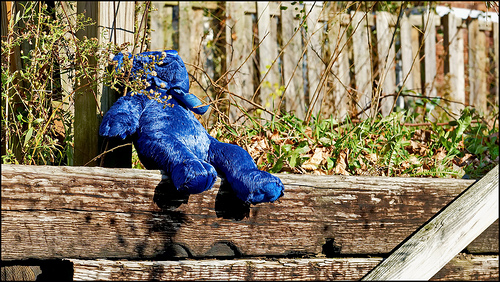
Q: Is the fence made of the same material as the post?
A: Yes, both the fence and the post are made of wood.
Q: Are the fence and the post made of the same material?
A: Yes, both the fence and the post are made of wood.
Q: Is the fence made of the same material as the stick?
A: Yes, both the fence and the stick are made of wood.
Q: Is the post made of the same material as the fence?
A: Yes, both the post and the fence are made of wood.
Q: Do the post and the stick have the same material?
A: Yes, both the post and the stick are made of wood.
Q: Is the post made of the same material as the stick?
A: Yes, both the post and the stick are made of wood.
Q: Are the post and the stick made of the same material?
A: Yes, both the post and the stick are made of wood.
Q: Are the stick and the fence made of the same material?
A: Yes, both the stick and the fence are made of wood.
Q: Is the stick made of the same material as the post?
A: Yes, both the stick and the post are made of wood.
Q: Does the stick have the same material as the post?
A: Yes, both the stick and the post are made of wood.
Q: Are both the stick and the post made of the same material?
A: Yes, both the stick and the post are made of wood.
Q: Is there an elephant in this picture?
A: Yes, there is an elephant.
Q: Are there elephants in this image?
A: Yes, there is an elephant.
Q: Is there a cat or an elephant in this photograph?
A: Yes, there is an elephant.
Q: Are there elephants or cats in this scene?
A: Yes, there is an elephant.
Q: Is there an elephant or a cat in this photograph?
A: Yes, there is an elephant.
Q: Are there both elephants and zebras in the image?
A: No, there is an elephant but no zebras.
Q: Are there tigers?
A: No, there are no tigers.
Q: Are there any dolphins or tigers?
A: No, there are no tigers or dolphins.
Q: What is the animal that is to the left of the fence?
A: The animal is an elephant.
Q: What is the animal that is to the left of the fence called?
A: The animal is an elephant.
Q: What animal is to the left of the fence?
A: The animal is an elephant.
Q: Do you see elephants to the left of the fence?
A: Yes, there is an elephant to the left of the fence.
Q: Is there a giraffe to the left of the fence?
A: No, there is an elephant to the left of the fence.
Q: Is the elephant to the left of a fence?
A: Yes, the elephant is to the left of a fence.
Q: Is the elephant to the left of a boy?
A: No, the elephant is to the left of a fence.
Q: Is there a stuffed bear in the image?
A: Yes, there is a stuffed bear.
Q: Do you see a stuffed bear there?
A: Yes, there is a stuffed bear.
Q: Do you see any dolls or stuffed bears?
A: Yes, there is a stuffed bear.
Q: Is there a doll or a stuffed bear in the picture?
A: Yes, there is a stuffed bear.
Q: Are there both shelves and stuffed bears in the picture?
A: No, there is a stuffed bear but no shelves.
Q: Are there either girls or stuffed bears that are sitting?
A: Yes, the stuffed bear is sitting.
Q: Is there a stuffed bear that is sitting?
A: Yes, there is a stuffed bear that is sitting.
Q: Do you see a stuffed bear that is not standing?
A: Yes, there is a stuffed bear that is sitting .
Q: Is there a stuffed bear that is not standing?
A: Yes, there is a stuffed bear that is sitting.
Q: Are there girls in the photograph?
A: No, there are no girls.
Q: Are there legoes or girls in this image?
A: No, there are no girls or legoes.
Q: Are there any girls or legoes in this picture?
A: No, there are no girls or legoes.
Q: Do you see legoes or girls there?
A: No, there are no girls or legoes.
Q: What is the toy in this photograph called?
A: The toy is a stuffed bear.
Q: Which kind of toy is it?
A: The toy is a stuffed bear.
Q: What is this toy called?
A: This is a stuffed bear.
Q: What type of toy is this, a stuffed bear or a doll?
A: This is a stuffed bear.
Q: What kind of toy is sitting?
A: The toy is a stuffed bear.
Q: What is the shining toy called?
A: The toy is a stuffed bear.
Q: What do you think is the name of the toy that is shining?
A: The toy is a stuffed bear.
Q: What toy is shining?
A: The toy is a stuffed bear.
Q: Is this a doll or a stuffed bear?
A: This is a stuffed bear.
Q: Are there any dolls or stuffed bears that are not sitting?
A: No, there is a stuffed bear but it is sitting.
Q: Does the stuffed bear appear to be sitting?
A: Yes, the stuffed bear is sitting.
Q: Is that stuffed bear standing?
A: No, the stuffed bear is sitting.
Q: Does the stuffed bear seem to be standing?
A: No, the stuffed bear is sitting.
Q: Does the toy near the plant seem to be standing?
A: No, the stuffed bear is sitting.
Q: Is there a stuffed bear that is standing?
A: No, there is a stuffed bear but it is sitting.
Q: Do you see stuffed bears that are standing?
A: No, there is a stuffed bear but it is sitting.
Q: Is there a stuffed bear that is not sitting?
A: No, there is a stuffed bear but it is sitting.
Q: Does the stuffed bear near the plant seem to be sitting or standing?
A: The stuffed bear is sitting.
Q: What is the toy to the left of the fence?
A: The toy is a stuffed bear.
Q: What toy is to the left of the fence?
A: The toy is a stuffed bear.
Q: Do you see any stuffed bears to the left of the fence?
A: Yes, there is a stuffed bear to the left of the fence.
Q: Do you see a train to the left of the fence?
A: No, there is a stuffed bear to the left of the fence.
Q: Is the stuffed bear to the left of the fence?
A: Yes, the stuffed bear is to the left of the fence.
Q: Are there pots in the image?
A: No, there are no pots.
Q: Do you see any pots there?
A: No, there are no pots.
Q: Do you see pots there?
A: No, there are no pots.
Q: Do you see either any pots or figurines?
A: No, there are no pots or figurines.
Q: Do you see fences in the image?
A: Yes, there is a fence.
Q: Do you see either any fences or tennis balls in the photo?
A: Yes, there is a fence.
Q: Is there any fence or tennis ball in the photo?
A: Yes, there is a fence.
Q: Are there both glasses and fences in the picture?
A: No, there is a fence but no glasses.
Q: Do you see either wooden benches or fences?
A: Yes, there is a wood fence.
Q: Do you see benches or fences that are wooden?
A: Yes, the fence is wooden.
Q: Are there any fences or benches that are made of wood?
A: Yes, the fence is made of wood.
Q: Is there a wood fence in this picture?
A: Yes, there is a wood fence.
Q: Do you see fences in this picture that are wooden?
A: Yes, there is a fence that is wooden.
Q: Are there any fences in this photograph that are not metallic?
A: Yes, there is a wooden fence.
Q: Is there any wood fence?
A: Yes, there is a fence that is made of wood.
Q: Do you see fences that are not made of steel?
A: Yes, there is a fence that is made of wood.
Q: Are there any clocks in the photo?
A: No, there are no clocks.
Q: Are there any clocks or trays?
A: No, there are no clocks or trays.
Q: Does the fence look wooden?
A: Yes, the fence is wooden.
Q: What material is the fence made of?
A: The fence is made of wood.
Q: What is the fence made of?
A: The fence is made of wood.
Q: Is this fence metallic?
A: No, the fence is wooden.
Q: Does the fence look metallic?
A: No, the fence is wooden.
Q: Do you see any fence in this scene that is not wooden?
A: No, there is a fence but it is wooden.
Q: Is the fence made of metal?
A: No, the fence is made of wood.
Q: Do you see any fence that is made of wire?
A: No, there is a fence but it is made of wood.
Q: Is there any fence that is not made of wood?
A: No, there is a fence but it is made of wood.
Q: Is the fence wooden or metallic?
A: The fence is wooden.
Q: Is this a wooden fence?
A: Yes, this is a wooden fence.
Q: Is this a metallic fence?
A: No, this is a wooden fence.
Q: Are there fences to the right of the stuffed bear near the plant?
A: Yes, there is a fence to the right of the stuffed bear.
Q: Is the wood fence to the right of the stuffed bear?
A: Yes, the fence is to the right of the stuffed bear.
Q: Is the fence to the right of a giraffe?
A: No, the fence is to the right of the stuffed bear.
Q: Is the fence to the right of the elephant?
A: Yes, the fence is to the right of the elephant.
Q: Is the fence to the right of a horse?
A: No, the fence is to the right of the elephant.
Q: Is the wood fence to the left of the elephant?
A: No, the fence is to the right of the elephant.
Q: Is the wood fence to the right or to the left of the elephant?
A: The fence is to the right of the elephant.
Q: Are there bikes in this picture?
A: No, there are no bikes.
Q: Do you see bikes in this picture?
A: No, there are no bikes.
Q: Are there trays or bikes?
A: No, there are no bikes or trays.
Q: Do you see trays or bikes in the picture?
A: No, there are no bikes or trays.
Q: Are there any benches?
A: No, there are no benches.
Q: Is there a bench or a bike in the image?
A: No, there are no benches or bikes.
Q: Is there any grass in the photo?
A: Yes, there is grass.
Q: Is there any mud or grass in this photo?
A: Yes, there is grass.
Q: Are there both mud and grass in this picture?
A: No, there is grass but no mud.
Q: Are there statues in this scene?
A: No, there are no statues.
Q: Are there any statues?
A: No, there are no statues.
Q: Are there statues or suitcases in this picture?
A: No, there are no statues or suitcases.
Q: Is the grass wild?
A: Yes, the grass is wild.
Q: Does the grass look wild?
A: Yes, the grass is wild.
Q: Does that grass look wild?
A: Yes, the grass is wild.